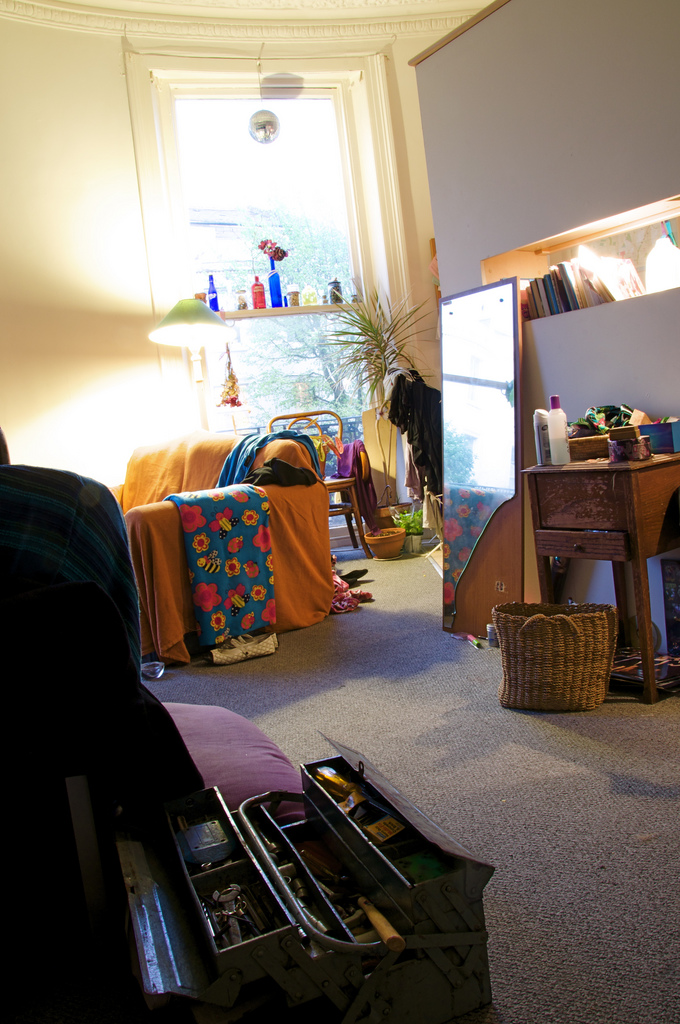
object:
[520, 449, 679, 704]
table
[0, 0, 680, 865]
floor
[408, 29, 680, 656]
wall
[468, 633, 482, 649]
tube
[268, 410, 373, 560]
chair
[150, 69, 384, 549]
window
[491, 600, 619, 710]
bag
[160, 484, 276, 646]
blanket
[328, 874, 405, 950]
hammer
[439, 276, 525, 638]
mirror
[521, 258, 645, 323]
books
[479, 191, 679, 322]
shelf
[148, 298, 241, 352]
lamp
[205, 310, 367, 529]
glass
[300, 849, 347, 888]
tool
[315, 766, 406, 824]
tool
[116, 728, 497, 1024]
bag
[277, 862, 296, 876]
tool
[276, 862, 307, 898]
tool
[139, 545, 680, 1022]
carpet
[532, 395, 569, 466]
bottle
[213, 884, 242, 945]
tool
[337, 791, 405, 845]
tool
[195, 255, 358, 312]
bottles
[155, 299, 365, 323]
ledge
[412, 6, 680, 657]
white wall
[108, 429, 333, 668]
chair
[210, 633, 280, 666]
shoe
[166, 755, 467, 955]
tools